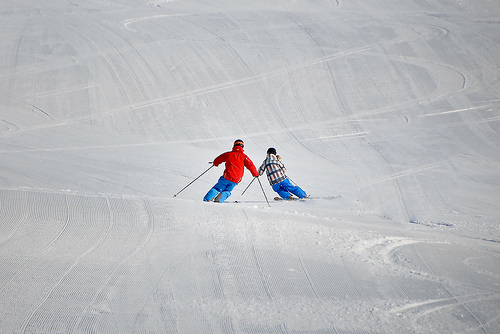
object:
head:
[234, 139, 245, 150]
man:
[202, 139, 259, 203]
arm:
[213, 152, 227, 166]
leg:
[206, 181, 227, 199]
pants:
[203, 176, 238, 203]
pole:
[174, 164, 215, 197]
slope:
[0, 1, 499, 333]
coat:
[213, 146, 259, 184]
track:
[378, 239, 499, 334]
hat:
[267, 147, 276, 155]